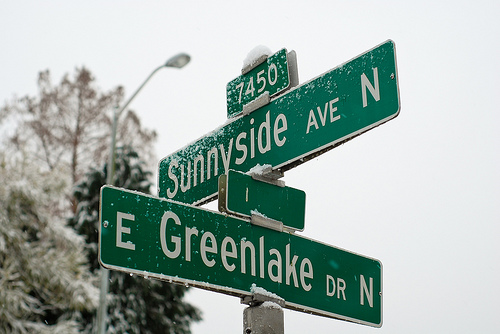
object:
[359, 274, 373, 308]
letter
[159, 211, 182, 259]
letter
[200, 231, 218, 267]
letter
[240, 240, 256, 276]
letter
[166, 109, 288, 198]
letter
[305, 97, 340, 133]
letter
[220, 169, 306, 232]
empty sign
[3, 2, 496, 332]
sky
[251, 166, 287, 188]
brackets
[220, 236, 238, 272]
letter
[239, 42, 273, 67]
snow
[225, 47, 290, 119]
sign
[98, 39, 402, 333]
cluster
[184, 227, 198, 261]
letter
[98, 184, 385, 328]
sign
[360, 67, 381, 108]
letter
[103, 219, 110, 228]
bolt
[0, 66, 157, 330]
snow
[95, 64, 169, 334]
pole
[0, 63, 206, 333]
tree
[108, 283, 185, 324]
leaves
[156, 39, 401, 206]
sign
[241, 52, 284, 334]
pole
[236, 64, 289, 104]
letter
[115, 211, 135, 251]
letter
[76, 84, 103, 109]
leaves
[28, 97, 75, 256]
snow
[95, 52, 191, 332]
light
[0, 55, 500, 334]
street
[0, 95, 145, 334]
snow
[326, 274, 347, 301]
letters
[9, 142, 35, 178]
leaves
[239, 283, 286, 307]
bottom